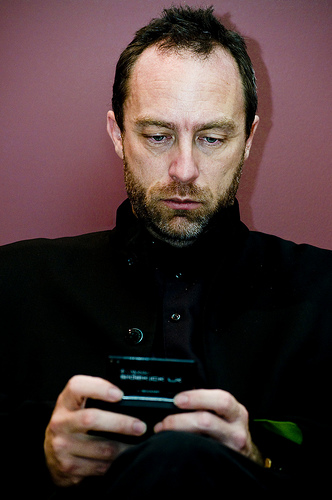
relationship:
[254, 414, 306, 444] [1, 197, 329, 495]
lining on jacket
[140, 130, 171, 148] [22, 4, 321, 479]
eye of man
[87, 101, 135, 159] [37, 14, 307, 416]
ear of man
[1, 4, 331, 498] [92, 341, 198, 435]
man holding device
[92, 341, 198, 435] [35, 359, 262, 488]
device in hand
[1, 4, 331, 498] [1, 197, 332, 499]
man wearing jacket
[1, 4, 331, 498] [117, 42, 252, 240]
man has face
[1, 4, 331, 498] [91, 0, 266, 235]
man has head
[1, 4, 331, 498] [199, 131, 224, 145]
man has eye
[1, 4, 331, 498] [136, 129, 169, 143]
man has eye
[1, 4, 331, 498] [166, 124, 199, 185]
man has nose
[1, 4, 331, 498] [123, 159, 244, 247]
man has beard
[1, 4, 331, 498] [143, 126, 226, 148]
man has eyes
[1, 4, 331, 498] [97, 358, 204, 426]
man holding device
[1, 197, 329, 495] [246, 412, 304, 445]
jacket has pocket liner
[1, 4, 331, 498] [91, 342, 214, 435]
man looking at device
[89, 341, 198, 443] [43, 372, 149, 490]
device in hand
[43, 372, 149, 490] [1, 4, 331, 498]
hand on man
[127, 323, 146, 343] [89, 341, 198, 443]
light on device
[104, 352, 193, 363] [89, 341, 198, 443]
light on device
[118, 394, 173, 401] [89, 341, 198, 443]
light on device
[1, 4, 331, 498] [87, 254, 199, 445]
man starring intently at device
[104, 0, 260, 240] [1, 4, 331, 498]
head of man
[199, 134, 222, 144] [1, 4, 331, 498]
eye on man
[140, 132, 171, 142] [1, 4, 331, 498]
eye on man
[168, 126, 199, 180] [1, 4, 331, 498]
nose of a man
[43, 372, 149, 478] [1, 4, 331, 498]
hand on man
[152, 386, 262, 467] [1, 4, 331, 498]
hand on man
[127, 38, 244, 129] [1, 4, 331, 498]
forehead on man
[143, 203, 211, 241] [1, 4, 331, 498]
chin on man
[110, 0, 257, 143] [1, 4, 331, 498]
hair on man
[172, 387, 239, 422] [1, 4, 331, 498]
finger on man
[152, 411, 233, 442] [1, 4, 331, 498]
finger on man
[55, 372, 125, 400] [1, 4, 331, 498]
finger on man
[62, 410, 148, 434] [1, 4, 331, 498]
finger on man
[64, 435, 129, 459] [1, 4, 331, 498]
finger on man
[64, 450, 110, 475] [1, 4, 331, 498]
finger on man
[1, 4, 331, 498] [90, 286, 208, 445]
man holding phone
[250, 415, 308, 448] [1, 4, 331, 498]
fabric on man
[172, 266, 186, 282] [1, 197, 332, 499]
button on jacket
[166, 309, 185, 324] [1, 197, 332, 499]
button on jacket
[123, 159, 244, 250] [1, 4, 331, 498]
beard on man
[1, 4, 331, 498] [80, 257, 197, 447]
man looking at phone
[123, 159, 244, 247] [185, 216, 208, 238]
beard has patch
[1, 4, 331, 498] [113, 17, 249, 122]
man has hairline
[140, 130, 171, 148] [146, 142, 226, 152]
eye have bags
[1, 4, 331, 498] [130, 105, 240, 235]
man has expression